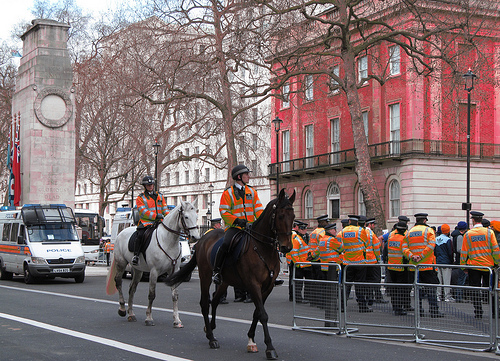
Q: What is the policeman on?
A: The policeman is on a brown horse.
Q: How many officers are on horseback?
A: There are two officers on horseback.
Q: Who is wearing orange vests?
A: Police officers.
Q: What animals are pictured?
A: Horses.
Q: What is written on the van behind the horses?
A: "Police".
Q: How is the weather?
A: Cold.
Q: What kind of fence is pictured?
A: A metal barricade.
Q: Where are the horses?
A: In a street.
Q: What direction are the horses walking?
A: To the right.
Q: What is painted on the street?
A: Two white lines.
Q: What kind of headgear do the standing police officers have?
A: Peaked caps.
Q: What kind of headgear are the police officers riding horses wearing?
A: Helmets.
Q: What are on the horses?
A: 2 men.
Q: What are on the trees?
A: Nothing.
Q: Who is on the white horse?
A: A police officer.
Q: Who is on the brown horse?
A: A police officer.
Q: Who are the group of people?
A: A group of police officers.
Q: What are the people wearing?
A: Orange vests.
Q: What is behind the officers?
A: A red building.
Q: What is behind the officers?
A: Several buildings.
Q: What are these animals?
A: Horses.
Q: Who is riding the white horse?
A: A police officer.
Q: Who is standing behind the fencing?
A: Police.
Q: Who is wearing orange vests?
A: Police.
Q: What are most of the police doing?
A: Standing on the street.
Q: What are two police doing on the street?
A: Riding horses.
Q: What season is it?
A: Winter.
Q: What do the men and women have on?
A: The same jackets.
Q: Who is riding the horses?
A: Two people.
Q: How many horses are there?
A: Two.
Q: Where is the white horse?
A: Behind the other horse.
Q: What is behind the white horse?
A: A small bus.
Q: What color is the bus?
A: White.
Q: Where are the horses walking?
A: On the street.